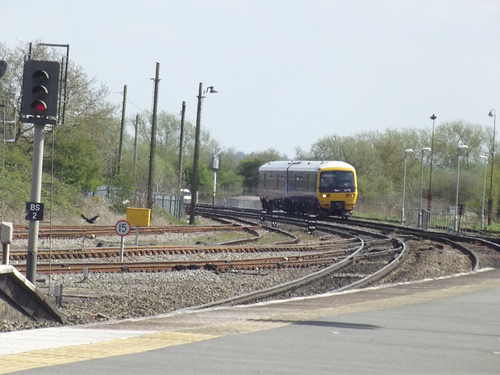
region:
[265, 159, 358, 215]
Short train on railroad tracks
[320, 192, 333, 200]
Headlight on front of train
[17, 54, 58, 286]
Traffic light beside train tracks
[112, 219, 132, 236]
Round sign with number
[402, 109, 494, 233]
Street lights standing beside train tracks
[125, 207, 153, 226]
Square yellow box on a post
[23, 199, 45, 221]
Small black sign on pole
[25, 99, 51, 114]
Red light on traffic pole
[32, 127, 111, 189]
Green bush near tracks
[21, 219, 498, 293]
May different railroad tracks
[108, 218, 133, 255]
a small round sign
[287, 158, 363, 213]
a yellow and silver train car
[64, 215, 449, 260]
several sets of train tracks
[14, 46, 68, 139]
a traffic signal next to a train track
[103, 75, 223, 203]
several wood electrical poles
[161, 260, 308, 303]
gravel next to a train track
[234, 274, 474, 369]
a concrete platform next to train tracks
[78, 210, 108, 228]
a bird flying in the air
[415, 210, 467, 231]
a metal fence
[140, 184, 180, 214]
a tall chain link fence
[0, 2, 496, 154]
blue of daytime sky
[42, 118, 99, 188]
green leaves on trees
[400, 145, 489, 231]
lights on top of poles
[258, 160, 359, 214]
commuter train on tracks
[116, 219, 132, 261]
round sign with number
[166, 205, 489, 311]
curve of train tracks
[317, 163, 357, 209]
yellow face of train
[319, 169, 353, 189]
window on front of train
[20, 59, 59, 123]
glowing red traffic light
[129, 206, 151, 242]
yellow box on pole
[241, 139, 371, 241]
train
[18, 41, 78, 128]
signal light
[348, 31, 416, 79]
white clouds in blue sky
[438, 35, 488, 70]
white clouds in blue sky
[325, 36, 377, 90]
white clouds in blue sky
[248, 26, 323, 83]
white clouds in blue sky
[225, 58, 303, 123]
white clouds in blue sky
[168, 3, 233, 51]
white clouds in blue sky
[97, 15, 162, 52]
white clouds in blue sky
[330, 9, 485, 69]
white clouds in blue sky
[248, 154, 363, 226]
The train is short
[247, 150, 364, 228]
The train is yellow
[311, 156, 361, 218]
The train's headlights are on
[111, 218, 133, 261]
Speed limit is 15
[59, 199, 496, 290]
There are many train tracks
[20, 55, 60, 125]
The traffic light is red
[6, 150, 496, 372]
The train platform is empty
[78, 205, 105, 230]
A bird is flying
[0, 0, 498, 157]
The sky is gray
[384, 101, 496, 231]
The streetlights are not on